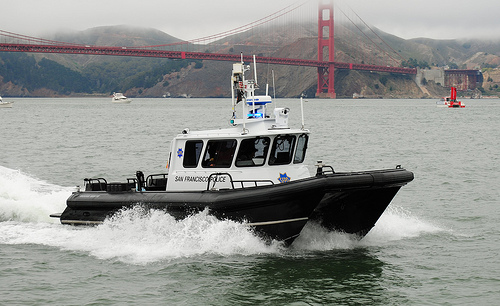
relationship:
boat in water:
[51, 50, 415, 248] [0, 95, 500, 303]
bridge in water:
[0, 0, 422, 98] [0, 95, 500, 303]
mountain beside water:
[2, 17, 500, 98] [0, 95, 500, 303]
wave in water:
[2, 167, 447, 265] [0, 95, 500, 303]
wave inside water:
[2, 167, 447, 265] [0, 95, 500, 303]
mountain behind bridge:
[2, 17, 500, 98] [0, 0, 422, 98]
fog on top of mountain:
[0, 0, 499, 43] [2, 17, 500, 98]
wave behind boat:
[2, 167, 447, 265] [51, 50, 415, 248]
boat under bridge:
[110, 92, 132, 104] [0, 0, 422, 98]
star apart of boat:
[278, 171, 293, 184] [51, 50, 415, 248]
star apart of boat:
[177, 149, 185, 157] [51, 50, 415, 248]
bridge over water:
[0, 0, 422, 98] [0, 95, 500, 303]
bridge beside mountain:
[0, 0, 422, 98] [2, 17, 500, 98]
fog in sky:
[0, 0, 499, 43] [0, 0, 499, 46]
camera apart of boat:
[274, 108, 291, 128] [51, 50, 415, 248]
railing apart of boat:
[205, 172, 275, 192] [51, 50, 415, 248]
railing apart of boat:
[86, 177, 106, 185] [51, 50, 415, 248]